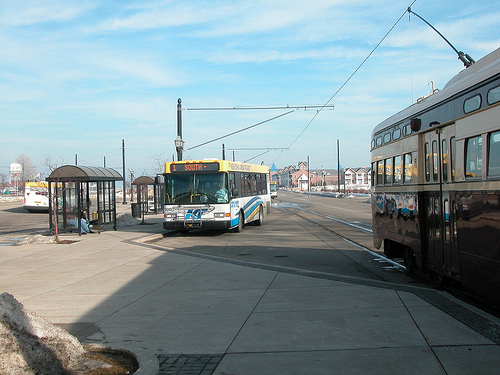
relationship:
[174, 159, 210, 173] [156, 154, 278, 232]
word written on bus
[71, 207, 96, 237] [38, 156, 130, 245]
person sitting on bus stop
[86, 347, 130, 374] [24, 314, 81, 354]
grass nex to snow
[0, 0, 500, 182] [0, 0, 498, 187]
clouds are on blue sky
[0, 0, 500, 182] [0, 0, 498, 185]
clouds are on sky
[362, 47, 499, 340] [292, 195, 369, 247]
bus driving on road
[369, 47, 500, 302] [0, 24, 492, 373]
bus in city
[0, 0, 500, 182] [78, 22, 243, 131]
clouds in sky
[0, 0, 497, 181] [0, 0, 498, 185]
clouds in sky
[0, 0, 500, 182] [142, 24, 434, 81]
clouds in sky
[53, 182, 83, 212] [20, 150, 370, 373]
clear cover at bus stop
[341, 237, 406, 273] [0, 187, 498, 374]
snow on street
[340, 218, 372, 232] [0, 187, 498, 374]
snow on street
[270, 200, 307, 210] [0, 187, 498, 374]
snow on street